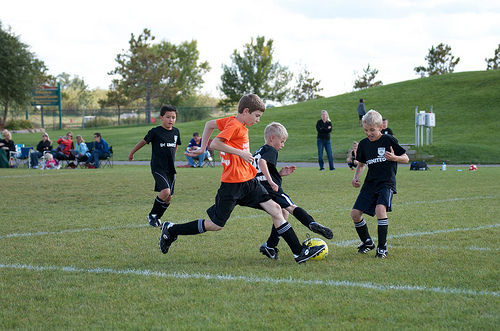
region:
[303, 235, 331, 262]
A yellow soccer ball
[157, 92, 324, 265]
A boy running for the ball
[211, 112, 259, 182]
An orange shirt on the boy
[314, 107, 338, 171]
A woman standing in the background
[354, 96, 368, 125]
A person standing on a hill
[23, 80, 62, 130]
A green sign with yellow writing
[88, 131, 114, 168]
A person in a blue shirt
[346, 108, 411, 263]
A boy wearing a black shirt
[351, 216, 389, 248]
Shin guards on the boy's legs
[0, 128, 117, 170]
People sitting on the sideline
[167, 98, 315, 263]
boy wearing black shorts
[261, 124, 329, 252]
boy wearing black shorts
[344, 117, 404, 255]
boy wearing black shorts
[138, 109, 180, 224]
boy wearing black shorts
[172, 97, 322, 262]
boy wearing black shoes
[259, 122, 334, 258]
boy wearing black shoes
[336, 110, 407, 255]
boy wearing black shoes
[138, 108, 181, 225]
boy wearing black shoes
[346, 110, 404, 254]
boy wearing black shirt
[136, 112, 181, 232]
boy wearing black shirt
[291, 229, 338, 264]
a yellow soccer ball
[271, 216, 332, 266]
a leg kicking a soccer ball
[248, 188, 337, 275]
a leg wearing a black sock and shoe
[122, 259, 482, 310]
a white line on the grass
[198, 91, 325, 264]
two boys playing soccer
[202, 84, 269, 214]
a boy in an orange shirt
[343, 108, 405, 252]
a boy in a soccer uniform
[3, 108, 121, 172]
people watching a soccer game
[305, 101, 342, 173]
a woman watching a sporting event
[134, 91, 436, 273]
four boys playing soccer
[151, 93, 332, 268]
kid wearing orange shirt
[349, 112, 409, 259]
kid wearing black shirt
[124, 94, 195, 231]
kid wearing black shorts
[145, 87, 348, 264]
kids kicking the ball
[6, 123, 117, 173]
people sitting down on grass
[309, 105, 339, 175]
person wearing blue jeans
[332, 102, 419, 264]
kid wearing black socks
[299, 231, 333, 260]
yellow soccer ball on field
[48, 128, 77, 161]
person wearing red jacket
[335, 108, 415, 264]
kid wearing a soccer shoe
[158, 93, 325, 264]
a young boy running on field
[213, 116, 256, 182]
a bright orange jersey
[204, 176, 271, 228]
a pair of black shorts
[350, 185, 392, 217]
a pair of black shorts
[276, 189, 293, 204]
a pair of black shorts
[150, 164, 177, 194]
a pair of black shorts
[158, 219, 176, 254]
a pair of black and white shoes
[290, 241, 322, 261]
a pair of black and white shoes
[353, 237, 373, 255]
a pair of black and white shoes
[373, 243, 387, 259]
a pair of black and white shoes